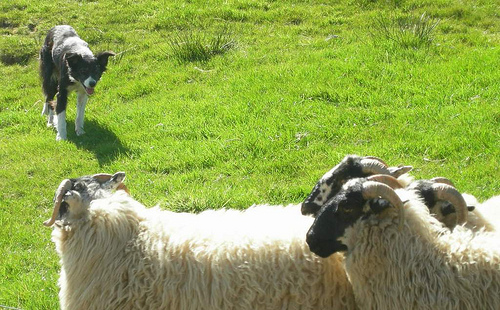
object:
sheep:
[298, 155, 426, 218]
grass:
[351, 5, 443, 52]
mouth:
[82, 84, 97, 96]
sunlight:
[92, 188, 313, 256]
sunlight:
[393, 165, 500, 261]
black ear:
[99, 50, 113, 63]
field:
[1, 0, 500, 309]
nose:
[87, 78, 97, 87]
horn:
[363, 180, 407, 235]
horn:
[39, 177, 81, 227]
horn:
[362, 159, 395, 176]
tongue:
[86, 87, 96, 95]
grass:
[157, 27, 243, 64]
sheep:
[300, 173, 500, 308]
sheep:
[400, 176, 500, 237]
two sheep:
[299, 151, 498, 308]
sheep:
[43, 170, 359, 309]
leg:
[74, 87, 88, 128]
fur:
[103, 218, 267, 308]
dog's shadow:
[60, 117, 149, 170]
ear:
[102, 171, 129, 191]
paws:
[54, 125, 73, 141]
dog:
[34, 21, 118, 145]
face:
[300, 179, 359, 250]